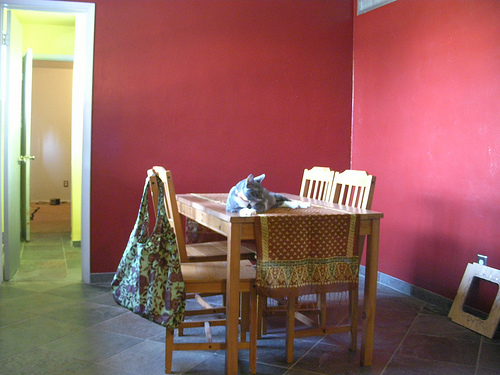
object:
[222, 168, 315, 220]
cat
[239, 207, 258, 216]
feet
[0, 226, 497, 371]
floor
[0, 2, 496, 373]
dining room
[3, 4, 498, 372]
room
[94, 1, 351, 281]
wall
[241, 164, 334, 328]
chair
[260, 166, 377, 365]
chair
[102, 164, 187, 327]
small train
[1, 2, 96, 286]
frame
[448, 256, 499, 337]
wood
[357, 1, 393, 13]
vent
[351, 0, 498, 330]
wall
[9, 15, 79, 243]
wall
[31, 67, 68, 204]
wall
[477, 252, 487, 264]
outlet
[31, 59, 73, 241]
doorway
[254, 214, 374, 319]
runner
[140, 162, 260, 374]
chair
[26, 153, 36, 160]
doorknob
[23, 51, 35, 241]
door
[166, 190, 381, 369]
table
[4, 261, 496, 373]
tile floor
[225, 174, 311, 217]
cat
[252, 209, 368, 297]
table cloth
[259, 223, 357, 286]
brown,yellow,green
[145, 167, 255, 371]
chair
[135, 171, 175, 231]
strap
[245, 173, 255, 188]
ears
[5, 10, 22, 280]
door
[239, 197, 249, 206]
collar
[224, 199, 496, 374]
shadows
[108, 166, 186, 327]
bag